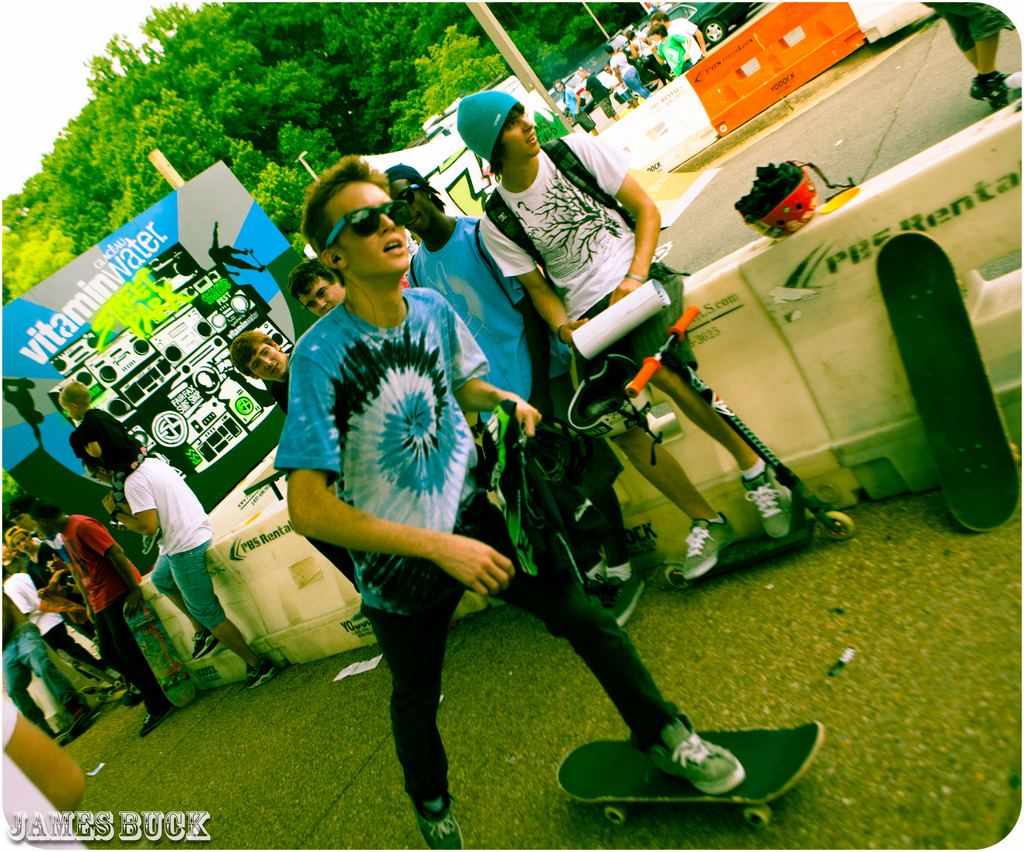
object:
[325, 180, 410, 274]
face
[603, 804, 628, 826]
wheel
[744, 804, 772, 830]
wheel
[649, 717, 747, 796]
foot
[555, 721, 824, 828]
skateboard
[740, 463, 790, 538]
feet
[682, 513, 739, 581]
feet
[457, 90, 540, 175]
head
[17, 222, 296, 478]
sign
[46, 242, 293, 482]
boom boxes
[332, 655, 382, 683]
paper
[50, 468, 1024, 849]
ground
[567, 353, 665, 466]
helmet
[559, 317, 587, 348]
hand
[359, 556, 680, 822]
feet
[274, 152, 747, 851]
boy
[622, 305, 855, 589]
scooter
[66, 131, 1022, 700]
wall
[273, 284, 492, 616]
shirt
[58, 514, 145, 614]
shirt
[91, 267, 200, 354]
letters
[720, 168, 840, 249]
helmet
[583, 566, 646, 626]
shoe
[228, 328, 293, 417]
person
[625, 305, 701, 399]
handles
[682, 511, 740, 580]
shoe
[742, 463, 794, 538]
shoe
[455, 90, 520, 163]
beanie cap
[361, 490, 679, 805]
jeans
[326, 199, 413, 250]
sunglasses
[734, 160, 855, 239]
helmet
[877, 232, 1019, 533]
skateboard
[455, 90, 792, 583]
boy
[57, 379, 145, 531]
child